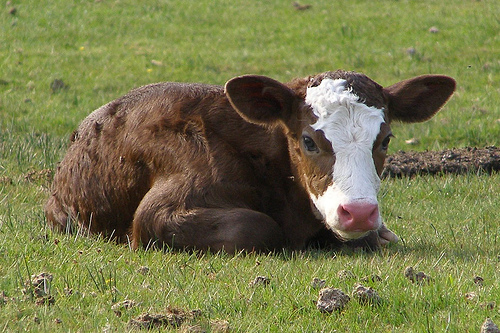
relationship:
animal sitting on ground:
[43, 70, 457, 259] [8, 227, 484, 319]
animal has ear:
[43, 70, 457, 259] [221, 70, 292, 132]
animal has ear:
[43, 70, 457, 259] [385, 70, 455, 125]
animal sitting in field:
[43, 70, 457, 259] [3, 217, 484, 331]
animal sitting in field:
[43, 70, 457, 259] [13, 32, 488, 331]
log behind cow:
[382, 127, 489, 205] [129, 87, 411, 259]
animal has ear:
[43, 70, 457, 259] [387, 69, 457, 130]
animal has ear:
[43, 70, 457, 259] [221, 66, 297, 133]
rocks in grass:
[20, 233, 498, 330] [6, 150, 484, 322]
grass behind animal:
[21, 12, 491, 332] [43, 70, 457, 259]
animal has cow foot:
[43, 70, 457, 259] [373, 217, 423, 248]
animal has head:
[35, 59, 456, 262] [223, 62, 462, 243]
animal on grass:
[43, 70, 457, 259] [426, 173, 466, 233]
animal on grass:
[43, 70, 457, 259] [2, 0, 498, 325]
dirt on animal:
[416, 127, 466, 189] [62, 42, 462, 287]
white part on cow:
[299, 75, 390, 247] [42, 61, 464, 260]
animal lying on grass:
[43, 70, 457, 259] [21, 12, 491, 332]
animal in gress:
[43, 70, 457, 259] [6, 258, 489, 327]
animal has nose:
[43, 70, 457, 259] [338, 201, 380, 233]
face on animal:
[246, 30, 434, 242] [43, 70, 457, 259]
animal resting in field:
[43, 70, 457, 259] [30, 15, 477, 311]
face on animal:
[294, 71, 395, 237] [43, 70, 457, 259]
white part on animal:
[299, 79, 390, 242] [43, 70, 457, 259]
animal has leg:
[43, 70, 457, 259] [130, 182, 282, 254]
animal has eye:
[43, 70, 457, 259] [300, 132, 320, 155]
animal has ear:
[43, 70, 457, 259] [223, 73, 300, 130]